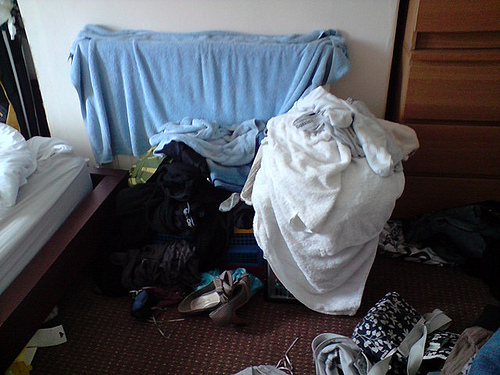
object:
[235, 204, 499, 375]
clothes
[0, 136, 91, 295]
bedsheet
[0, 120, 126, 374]
bed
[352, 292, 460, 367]
hand bag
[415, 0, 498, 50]
drawer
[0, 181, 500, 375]
red carpet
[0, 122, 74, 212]
net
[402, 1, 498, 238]
cabinet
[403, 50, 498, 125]
drawer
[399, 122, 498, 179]
drawer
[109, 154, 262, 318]
these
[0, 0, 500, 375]
room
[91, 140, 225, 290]
bags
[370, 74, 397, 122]
right